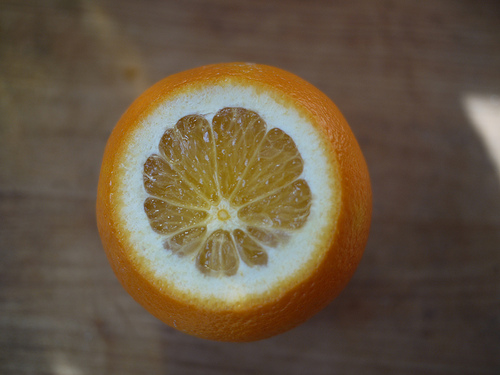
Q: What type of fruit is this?
A: An orange.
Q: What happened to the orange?
A: The top is sliced off.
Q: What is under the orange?
A: A table top.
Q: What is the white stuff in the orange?
A: The inside of the peel.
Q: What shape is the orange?
A: Round.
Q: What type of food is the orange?
A: A fruit.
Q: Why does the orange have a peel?
A: To protect the fruit inside.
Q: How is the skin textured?
A: Smooth but bumpy.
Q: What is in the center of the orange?
A: The edible fruit portion.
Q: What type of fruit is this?
A: Orange.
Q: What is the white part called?
A: Rind.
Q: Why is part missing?
A: Cut in half.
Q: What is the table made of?
A: Wood.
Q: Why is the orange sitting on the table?
A: It was just sliced.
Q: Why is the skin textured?
A: How it is made.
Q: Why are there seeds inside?
A: It is a fruit.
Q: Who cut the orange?
A: A person.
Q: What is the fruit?
A: An orange.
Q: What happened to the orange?
A: It is cut.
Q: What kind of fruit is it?
A: An orange.